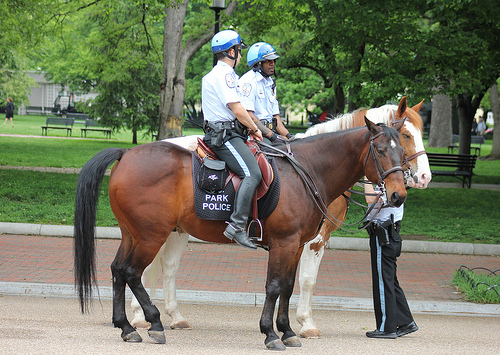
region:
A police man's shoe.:
[218, 204, 266, 264]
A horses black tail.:
[58, 132, 130, 319]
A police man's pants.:
[357, 207, 424, 352]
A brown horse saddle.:
[166, 108, 291, 246]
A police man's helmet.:
[237, 42, 299, 86]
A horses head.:
[344, 112, 411, 223]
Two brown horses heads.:
[328, 88, 468, 221]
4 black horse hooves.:
[92, 301, 324, 348]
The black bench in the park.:
[377, 115, 489, 190]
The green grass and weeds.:
[446, 257, 491, 311]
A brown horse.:
[115, 149, 376, 301]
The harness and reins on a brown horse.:
[318, 130, 412, 239]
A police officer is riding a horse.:
[126, 27, 295, 259]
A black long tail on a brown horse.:
[31, 139, 126, 306]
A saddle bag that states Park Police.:
[193, 184, 240, 219]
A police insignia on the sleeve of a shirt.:
[218, 70, 244, 92]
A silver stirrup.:
[228, 215, 280, 248]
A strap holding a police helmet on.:
[216, 47, 246, 67]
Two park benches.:
[31, 108, 117, 138]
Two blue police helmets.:
[198, 26, 283, 68]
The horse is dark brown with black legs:
[85, 125, 413, 353]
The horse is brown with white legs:
[132, 96, 433, 341]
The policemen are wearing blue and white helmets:
[213, 29, 279, 73]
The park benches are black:
[40, 109, 121, 139]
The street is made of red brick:
[7, 236, 497, 303]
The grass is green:
[2, 117, 498, 243]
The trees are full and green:
[10, 1, 489, 116]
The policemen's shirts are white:
[200, 61, 281, 133]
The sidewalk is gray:
[4, 160, 496, 207]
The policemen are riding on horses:
[61, 29, 433, 354]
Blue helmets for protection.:
[210, 25, 280, 87]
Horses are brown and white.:
[306, 101, 438, 211]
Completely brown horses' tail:
[63, 140, 142, 313]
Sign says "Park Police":
[196, 173, 236, 248]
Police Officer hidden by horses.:
[365, 175, 422, 346]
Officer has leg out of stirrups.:
[217, 136, 273, 251]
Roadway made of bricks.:
[5, 235, 76, 283]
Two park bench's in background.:
[31, 110, 120, 138]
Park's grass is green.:
[12, 137, 74, 212]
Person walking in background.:
[2, 86, 24, 136]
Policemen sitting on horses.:
[48, 22, 455, 349]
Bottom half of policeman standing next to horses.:
[361, 185, 452, 354]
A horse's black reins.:
[271, 134, 387, 234]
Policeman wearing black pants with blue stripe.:
[360, 225, 435, 337]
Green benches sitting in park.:
[40, 111, 123, 140]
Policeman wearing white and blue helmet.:
[208, 27, 247, 56]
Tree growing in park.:
[411, 7, 496, 194]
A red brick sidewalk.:
[13, 236, 72, 282]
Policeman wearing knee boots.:
[224, 178, 275, 255]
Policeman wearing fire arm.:
[199, 116, 238, 149]